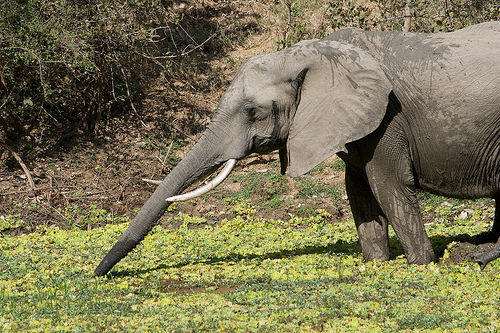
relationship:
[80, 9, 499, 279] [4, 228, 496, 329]
elephant has water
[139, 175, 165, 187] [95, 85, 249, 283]
tusk behind elephant trunk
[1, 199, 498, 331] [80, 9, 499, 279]
grass under elephant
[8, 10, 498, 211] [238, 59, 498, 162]
hill behind elephant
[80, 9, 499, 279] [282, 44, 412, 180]
elephant has ear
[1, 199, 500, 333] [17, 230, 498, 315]
grass in water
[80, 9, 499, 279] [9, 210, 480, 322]
elephant standing in grass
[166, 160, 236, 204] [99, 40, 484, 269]
tusk on elephant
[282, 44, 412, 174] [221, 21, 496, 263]
ear of elephant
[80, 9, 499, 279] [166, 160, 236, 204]
elephant has tusk